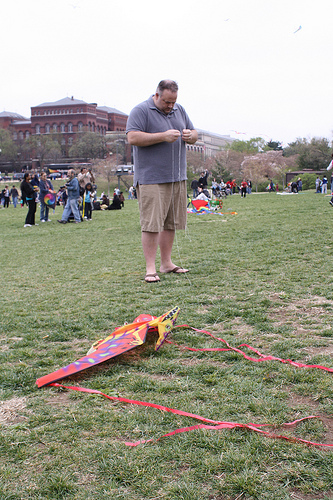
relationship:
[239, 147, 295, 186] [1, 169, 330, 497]
tree in park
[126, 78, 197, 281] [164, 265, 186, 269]
man wearing flip flops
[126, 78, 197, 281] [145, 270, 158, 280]
man wearing flip flops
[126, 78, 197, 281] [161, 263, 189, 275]
man wearing shoe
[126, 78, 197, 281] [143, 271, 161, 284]
man wearing shoe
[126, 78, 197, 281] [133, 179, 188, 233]
man wearing shorts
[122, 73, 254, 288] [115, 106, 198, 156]
man wearing shirt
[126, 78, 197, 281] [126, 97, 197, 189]
man wearing shirt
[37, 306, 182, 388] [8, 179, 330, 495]
kite on grass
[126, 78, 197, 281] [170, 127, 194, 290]
man working on string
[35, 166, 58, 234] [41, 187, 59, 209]
woman holding kite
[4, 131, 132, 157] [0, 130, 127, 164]
row of trees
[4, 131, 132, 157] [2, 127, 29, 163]
row of tree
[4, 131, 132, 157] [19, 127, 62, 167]
row of tree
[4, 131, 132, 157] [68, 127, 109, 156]
row of tree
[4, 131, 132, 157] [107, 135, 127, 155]
row of tree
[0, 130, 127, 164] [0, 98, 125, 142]
trees by building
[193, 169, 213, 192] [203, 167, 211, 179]
man holding object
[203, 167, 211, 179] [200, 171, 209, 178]
object in arm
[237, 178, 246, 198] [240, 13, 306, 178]
person with kite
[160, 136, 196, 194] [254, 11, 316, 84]
ribbons trailing from kite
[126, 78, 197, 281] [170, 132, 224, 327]
man attempting to fix string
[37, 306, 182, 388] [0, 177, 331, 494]
kite on grass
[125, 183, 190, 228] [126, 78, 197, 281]
shorts on man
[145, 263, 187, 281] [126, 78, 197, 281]
flip flops on man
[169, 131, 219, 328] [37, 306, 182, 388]
string of kite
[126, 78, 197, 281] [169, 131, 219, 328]
man focused on string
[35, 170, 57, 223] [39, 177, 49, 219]
jeans on woman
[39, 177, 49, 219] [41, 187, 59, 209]
woman holding kite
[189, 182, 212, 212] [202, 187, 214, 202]
person sitting in chair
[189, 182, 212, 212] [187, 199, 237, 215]
person surrounded by kites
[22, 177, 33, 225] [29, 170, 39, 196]
people holding child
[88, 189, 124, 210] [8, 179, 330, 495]
people sitting on grass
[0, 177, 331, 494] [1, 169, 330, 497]
grass of park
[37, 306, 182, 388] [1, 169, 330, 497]
kite in park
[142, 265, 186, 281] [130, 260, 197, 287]
flip flops on feet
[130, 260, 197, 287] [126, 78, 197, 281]
feet of man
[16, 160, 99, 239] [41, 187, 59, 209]
people standing with kite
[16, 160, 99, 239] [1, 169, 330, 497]
people in park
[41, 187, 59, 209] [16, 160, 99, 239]
kite in people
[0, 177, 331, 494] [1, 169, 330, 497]
grass in park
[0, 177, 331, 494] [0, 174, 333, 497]
grass on field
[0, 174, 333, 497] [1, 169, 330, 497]
field of park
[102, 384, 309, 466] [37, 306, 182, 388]
tail of kite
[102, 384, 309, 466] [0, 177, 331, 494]
tail on grass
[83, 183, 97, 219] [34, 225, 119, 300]
child walking towards camera